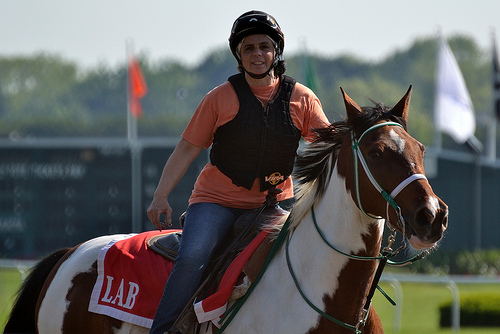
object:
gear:
[283, 117, 450, 331]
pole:
[436, 21, 439, 241]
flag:
[437, 42, 482, 145]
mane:
[265, 99, 400, 253]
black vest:
[210, 73, 299, 191]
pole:
[126, 50, 147, 234]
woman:
[148, 10, 345, 334]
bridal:
[143, 10, 386, 332]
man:
[143, 10, 380, 334]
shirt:
[180, 76, 336, 210]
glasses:
[245, 44, 271, 51]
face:
[241, 32, 274, 73]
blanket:
[84, 221, 278, 331]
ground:
[372, 279, 497, 333]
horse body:
[29, 223, 377, 334]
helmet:
[228, 10, 284, 50]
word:
[100, 274, 140, 310]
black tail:
[0, 246, 68, 334]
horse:
[0, 86, 449, 334]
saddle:
[222, 182, 297, 290]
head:
[228, 9, 286, 77]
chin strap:
[244, 64, 274, 79]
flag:
[127, 54, 147, 119]